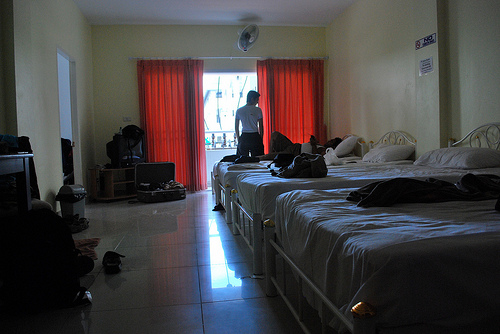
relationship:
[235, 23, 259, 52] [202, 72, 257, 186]
fan sitting above window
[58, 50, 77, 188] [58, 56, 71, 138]
doorway to room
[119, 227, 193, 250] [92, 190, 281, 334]
tile on floor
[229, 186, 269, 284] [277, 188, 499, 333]
footboard for bed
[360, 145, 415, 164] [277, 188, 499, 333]
pillow on top of bed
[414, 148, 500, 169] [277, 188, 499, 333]
pillow on top of bed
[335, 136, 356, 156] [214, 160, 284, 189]
pillow on top of bed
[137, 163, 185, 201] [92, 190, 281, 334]
suitcase on floor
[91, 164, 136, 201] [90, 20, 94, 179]
cabinet in corner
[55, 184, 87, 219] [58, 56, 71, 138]
trashcan in room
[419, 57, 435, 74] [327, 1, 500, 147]
picture on wall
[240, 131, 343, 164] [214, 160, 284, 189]
man on bed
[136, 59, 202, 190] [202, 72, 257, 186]
curtain on window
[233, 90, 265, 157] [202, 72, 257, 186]
man looking out window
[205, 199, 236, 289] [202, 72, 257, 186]
reflection from window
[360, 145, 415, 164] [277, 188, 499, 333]
pillow on bed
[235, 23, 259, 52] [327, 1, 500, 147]
fan attached to wall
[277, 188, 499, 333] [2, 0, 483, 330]
bed standing in room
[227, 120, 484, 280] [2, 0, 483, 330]
bed standing in room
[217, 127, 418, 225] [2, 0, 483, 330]
bed standing in room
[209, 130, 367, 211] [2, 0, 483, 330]
bed standing in room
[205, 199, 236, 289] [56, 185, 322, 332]
reflection seen in floor